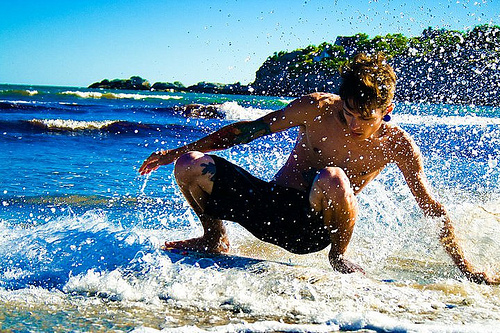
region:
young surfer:
[147, 63, 435, 304]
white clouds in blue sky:
[137, 6, 187, 37]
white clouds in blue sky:
[194, 35, 215, 63]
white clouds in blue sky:
[127, 46, 168, 70]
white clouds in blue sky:
[171, 29, 208, 56]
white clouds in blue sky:
[67, 29, 121, 57]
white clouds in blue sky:
[50, 15, 88, 42]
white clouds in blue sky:
[28, 13, 52, 40]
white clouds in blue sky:
[55, 11, 95, 35]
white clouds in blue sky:
[40, 35, 77, 50]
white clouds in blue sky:
[162, 13, 200, 55]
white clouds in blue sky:
[177, 15, 224, 60]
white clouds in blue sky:
[97, 5, 142, 30]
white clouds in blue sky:
[152, 19, 194, 64]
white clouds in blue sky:
[80, 23, 117, 48]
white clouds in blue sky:
[37, 18, 84, 53]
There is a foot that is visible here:
[346, 257, 355, 284]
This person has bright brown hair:
[363, 70, 373, 95]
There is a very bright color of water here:
[69, 123, 76, 152]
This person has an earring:
[380, 98, 400, 127]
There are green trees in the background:
[409, 52, 432, 112]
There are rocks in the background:
[173, 90, 203, 162]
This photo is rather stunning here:
[96, 56, 226, 308]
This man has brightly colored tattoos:
[218, 108, 252, 203]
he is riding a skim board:
[112, 26, 492, 326]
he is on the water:
[114, 43, 495, 302]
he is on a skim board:
[122, 43, 498, 301]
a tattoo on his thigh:
[190, 148, 232, 199]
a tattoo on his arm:
[192, 105, 300, 152]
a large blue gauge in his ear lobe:
[380, 109, 393, 124]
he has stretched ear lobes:
[330, 45, 412, 151]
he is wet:
[125, 36, 495, 323]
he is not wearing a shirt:
[113, 40, 495, 310]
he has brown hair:
[340, 45, 399, 115]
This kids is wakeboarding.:
[131, 53, 490, 287]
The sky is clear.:
[6, 3, 495, 86]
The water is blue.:
[18, 135, 160, 203]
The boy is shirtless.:
[130, 53, 495, 277]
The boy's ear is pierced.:
[376, 104, 396, 126]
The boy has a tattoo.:
[206, 119, 300, 143]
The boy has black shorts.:
[197, 149, 351, 265]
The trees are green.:
[254, 23, 496, 100]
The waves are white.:
[5, 86, 492, 141]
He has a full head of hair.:
[339, 56, 394, 113]